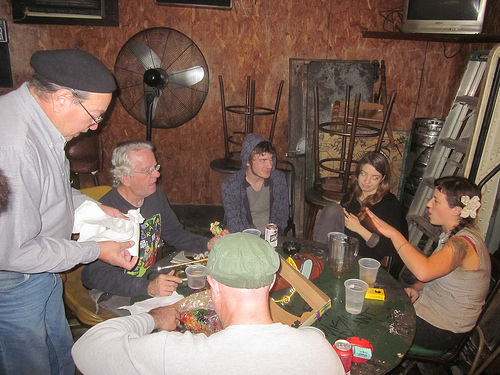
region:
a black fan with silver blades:
[112, 25, 209, 142]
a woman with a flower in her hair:
[363, 174, 493, 350]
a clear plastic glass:
[341, 278, 366, 319]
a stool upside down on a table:
[204, 70, 282, 176]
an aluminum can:
[262, 220, 279, 246]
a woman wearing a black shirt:
[340, 150, 406, 253]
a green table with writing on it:
[130, 230, 414, 372]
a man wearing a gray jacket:
[219, 133, 291, 233]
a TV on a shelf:
[363, 0, 498, 44]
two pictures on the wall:
[12, 0, 233, 25]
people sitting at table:
[72, 135, 483, 373]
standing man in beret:
[1, 48, 137, 373]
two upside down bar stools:
[216, 75, 396, 202]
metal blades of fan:
[135, 43, 203, 118]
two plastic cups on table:
[342, 255, 378, 315]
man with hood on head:
[222, 134, 287, 232]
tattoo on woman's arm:
[445, 238, 470, 270]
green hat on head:
[206, 233, 279, 291]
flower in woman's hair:
[458, 193, 480, 218]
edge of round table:
[356, 257, 416, 374]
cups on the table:
[310, 219, 393, 327]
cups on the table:
[312, 224, 386, 325]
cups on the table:
[311, 239, 414, 345]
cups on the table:
[320, 218, 417, 370]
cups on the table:
[328, 256, 408, 345]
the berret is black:
[22, 42, 130, 121]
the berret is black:
[30, 36, 129, 103]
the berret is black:
[0, 39, 142, 129]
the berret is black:
[8, 25, 159, 142]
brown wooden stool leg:
[342, 93, 364, 193]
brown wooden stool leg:
[378, 90, 396, 150]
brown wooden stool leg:
[337, 85, 352, 184]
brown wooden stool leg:
[311, 84, 328, 182]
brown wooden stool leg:
[268, 80, 285, 136]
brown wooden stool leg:
[250, 78, 255, 129]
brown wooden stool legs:
[218, 73, 285, 159]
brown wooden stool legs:
[308, 82, 396, 194]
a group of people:
[2, 50, 499, 370]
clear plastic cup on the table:
[338, 273, 368, 315]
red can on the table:
[333, 337, 357, 374]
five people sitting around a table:
[66, 135, 493, 374]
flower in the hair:
[458, 192, 482, 221]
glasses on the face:
[129, 163, 167, 182]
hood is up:
[238, 131, 280, 184]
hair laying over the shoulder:
[355, 179, 394, 221]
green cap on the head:
[199, 232, 279, 289]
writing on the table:
[350, 307, 381, 333]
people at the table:
[87, 88, 472, 341]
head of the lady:
[393, 156, 490, 236]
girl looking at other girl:
[318, 135, 412, 214]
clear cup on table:
[318, 279, 380, 323]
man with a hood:
[218, 118, 304, 195]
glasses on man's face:
[120, 147, 183, 205]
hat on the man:
[179, 213, 299, 310]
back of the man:
[142, 215, 310, 354]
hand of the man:
[82, 217, 150, 283]